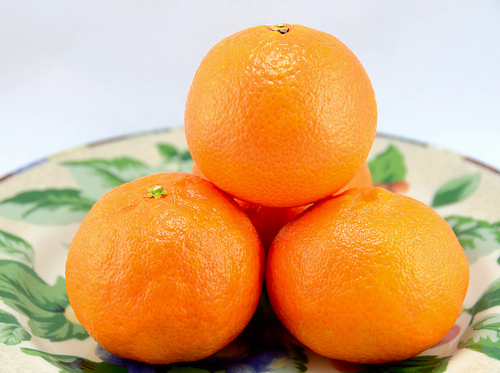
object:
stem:
[147, 183, 170, 198]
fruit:
[184, 22, 376, 205]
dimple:
[267, 76, 274, 84]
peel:
[236, 71, 328, 157]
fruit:
[65, 172, 266, 365]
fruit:
[267, 183, 471, 363]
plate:
[1, 126, 498, 372]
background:
[4, 6, 500, 187]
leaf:
[2, 186, 92, 218]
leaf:
[370, 143, 406, 188]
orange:
[191, 162, 373, 254]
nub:
[270, 22, 290, 34]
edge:
[3, 119, 500, 182]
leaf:
[0, 259, 88, 340]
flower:
[437, 325, 459, 346]